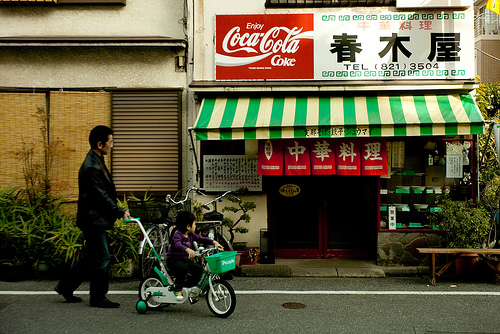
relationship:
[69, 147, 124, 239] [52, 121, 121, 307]
jacket of man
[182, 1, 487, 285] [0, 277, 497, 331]
storefront along street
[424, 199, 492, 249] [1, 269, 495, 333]
bush on roadway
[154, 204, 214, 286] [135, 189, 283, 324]
boy on bike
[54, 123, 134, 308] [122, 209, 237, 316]
man pushing bike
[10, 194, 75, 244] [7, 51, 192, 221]
bush by building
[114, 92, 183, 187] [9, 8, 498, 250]
window on building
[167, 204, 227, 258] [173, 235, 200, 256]
girl has arm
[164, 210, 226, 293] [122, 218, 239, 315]
boy on bicycle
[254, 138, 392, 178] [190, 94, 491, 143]
banners on awning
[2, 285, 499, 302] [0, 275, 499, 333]
white line on roadway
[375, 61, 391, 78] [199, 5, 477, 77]
black numbers on background